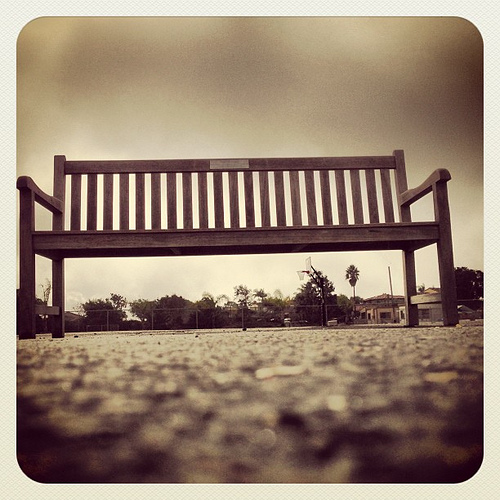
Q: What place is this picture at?
A: It is at the park.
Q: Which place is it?
A: It is a park.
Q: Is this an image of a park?
A: Yes, it is showing a park.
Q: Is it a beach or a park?
A: It is a park.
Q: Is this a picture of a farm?
A: No, the picture is showing a park.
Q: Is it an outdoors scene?
A: Yes, it is outdoors.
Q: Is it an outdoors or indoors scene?
A: It is outdoors.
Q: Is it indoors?
A: No, it is outdoors.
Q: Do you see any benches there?
A: Yes, there is a bench.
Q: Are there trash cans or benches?
A: Yes, there is a bench.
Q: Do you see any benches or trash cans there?
A: Yes, there is a bench.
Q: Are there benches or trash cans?
A: Yes, there is a bench.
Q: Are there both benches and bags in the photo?
A: No, there is a bench but no bags.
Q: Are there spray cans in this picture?
A: No, there are no spray cans.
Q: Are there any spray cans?
A: No, there are no spray cans.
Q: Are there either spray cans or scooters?
A: No, there are no spray cans or scooters.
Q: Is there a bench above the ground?
A: Yes, there is a bench above the ground.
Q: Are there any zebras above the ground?
A: No, there is a bench above the ground.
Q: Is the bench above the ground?
A: Yes, the bench is above the ground.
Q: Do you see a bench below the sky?
A: Yes, there is a bench below the sky.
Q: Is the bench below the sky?
A: Yes, the bench is below the sky.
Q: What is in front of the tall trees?
A: The bench is in front of the trees.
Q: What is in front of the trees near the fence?
A: The bench is in front of the trees.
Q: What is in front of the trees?
A: The bench is in front of the trees.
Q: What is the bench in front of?
A: The bench is in front of the trees.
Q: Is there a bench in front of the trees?
A: Yes, there is a bench in front of the trees.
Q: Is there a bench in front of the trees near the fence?
A: Yes, there is a bench in front of the trees.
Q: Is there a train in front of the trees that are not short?
A: No, there is a bench in front of the trees.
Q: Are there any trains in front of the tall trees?
A: No, there is a bench in front of the trees.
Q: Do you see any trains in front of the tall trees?
A: No, there is a bench in front of the trees.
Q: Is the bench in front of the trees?
A: Yes, the bench is in front of the trees.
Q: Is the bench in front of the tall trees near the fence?
A: Yes, the bench is in front of the trees.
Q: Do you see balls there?
A: No, there are no balls.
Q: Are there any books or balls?
A: No, there are no balls or books.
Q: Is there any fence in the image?
A: Yes, there is a fence.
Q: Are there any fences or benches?
A: Yes, there is a fence.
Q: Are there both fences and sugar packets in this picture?
A: No, there is a fence but no sugar packets.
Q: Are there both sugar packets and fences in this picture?
A: No, there is a fence but no sugar packets.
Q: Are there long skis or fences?
A: Yes, there is a long fence.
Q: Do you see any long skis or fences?
A: Yes, there is a long fence.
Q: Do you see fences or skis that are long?
A: Yes, the fence is long.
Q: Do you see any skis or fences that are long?
A: Yes, the fence is long.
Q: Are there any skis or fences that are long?
A: Yes, the fence is long.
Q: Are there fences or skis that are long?
A: Yes, the fence is long.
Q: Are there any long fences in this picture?
A: Yes, there is a long fence.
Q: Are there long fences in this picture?
A: Yes, there is a long fence.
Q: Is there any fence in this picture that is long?
A: Yes, there is a fence that is long.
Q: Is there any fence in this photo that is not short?
A: Yes, there is a long fence.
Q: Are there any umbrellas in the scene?
A: No, there are no umbrellas.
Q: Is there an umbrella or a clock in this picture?
A: No, there are no umbrellas or clocks.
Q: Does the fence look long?
A: Yes, the fence is long.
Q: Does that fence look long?
A: Yes, the fence is long.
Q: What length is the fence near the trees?
A: The fence is long.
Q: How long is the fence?
A: The fence is long.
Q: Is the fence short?
A: No, the fence is long.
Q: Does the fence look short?
A: No, the fence is long.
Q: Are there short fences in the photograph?
A: No, there is a fence but it is long.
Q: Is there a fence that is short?
A: No, there is a fence but it is long.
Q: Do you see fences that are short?
A: No, there is a fence but it is long.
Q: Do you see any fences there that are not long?
A: No, there is a fence but it is long.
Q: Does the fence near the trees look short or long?
A: The fence is long.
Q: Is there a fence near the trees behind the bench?
A: Yes, there is a fence near the trees.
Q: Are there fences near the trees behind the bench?
A: Yes, there is a fence near the trees.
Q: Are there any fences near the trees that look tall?
A: Yes, there is a fence near the trees.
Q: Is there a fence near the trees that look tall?
A: Yes, there is a fence near the trees.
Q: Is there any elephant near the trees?
A: No, there is a fence near the trees.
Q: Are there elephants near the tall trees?
A: No, there is a fence near the trees.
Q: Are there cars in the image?
A: No, there are no cars.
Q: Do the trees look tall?
A: Yes, the trees are tall.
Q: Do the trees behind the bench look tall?
A: Yes, the trees are tall.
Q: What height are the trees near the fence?
A: The trees are tall.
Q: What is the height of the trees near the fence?
A: The trees are tall.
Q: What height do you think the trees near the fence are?
A: The trees are tall.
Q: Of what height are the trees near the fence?
A: The trees are tall.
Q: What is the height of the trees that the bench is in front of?
A: The trees are tall.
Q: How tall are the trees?
A: The trees are tall.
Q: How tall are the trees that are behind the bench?
A: The trees are tall.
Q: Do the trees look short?
A: No, the trees are tall.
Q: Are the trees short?
A: No, the trees are tall.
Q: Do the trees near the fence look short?
A: No, the trees are tall.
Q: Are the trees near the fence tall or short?
A: The trees are tall.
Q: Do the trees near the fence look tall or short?
A: The trees are tall.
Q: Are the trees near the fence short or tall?
A: The trees are tall.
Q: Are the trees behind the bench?
A: Yes, the trees are behind the bench.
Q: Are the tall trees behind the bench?
A: Yes, the trees are behind the bench.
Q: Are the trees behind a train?
A: No, the trees are behind the bench.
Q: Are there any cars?
A: No, there are no cars.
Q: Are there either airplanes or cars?
A: No, there are no cars or airplanes.